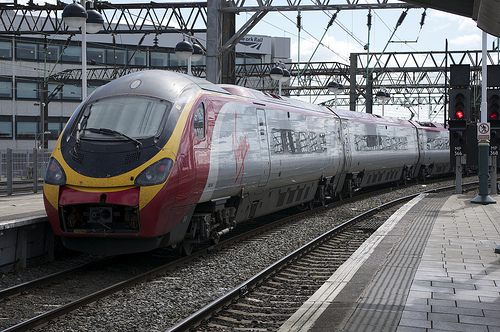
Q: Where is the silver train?
A: On tracks.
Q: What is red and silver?
A: Train car.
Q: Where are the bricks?
A: On platform.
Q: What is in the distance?
A: White building.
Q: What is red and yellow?
A: Train front.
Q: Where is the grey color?
A: Train back.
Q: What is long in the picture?
A: Train.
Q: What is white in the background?
A: Building.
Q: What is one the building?
A: Lots of glass windows.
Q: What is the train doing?
A: Sitting still.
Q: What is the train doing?
A: Waiting for passengers.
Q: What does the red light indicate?
A: Stop.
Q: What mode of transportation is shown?
A: A train.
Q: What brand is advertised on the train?
A: Virgin.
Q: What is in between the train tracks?
A: Rocks.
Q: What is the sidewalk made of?
A: Bricks.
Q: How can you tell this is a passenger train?
A: The windows.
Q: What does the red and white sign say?
A: No walking.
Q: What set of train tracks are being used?
A: Left tracks.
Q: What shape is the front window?
A: A rectangle.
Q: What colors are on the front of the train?
A: Black, yellow and red.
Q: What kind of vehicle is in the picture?
A: A train.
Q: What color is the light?
A: Red.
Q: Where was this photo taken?
A: A train stop.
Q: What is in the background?
A: A building.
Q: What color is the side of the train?
A: Grey.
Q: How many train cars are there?
A: Three.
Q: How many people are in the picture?
A: None.